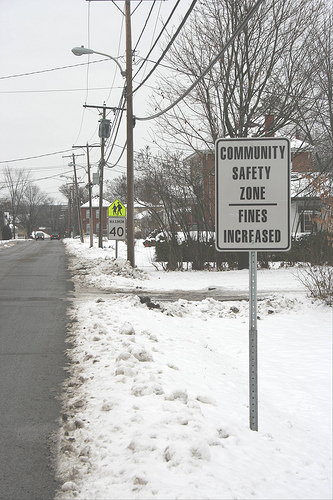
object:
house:
[79, 195, 111, 237]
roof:
[80, 195, 112, 208]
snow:
[268, 299, 333, 498]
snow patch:
[48, 382, 73, 473]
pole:
[248, 250, 258, 432]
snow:
[154, 320, 187, 334]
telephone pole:
[82, 101, 127, 249]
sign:
[107, 198, 126, 217]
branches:
[180, 0, 333, 139]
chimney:
[265, 114, 275, 137]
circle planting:
[289, 252, 333, 307]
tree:
[157, 0, 333, 138]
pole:
[125, 0, 136, 268]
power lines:
[151, 0, 197, 72]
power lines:
[105, 139, 127, 168]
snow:
[78, 452, 130, 500]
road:
[0, 245, 72, 500]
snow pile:
[90, 256, 152, 281]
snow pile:
[162, 296, 229, 318]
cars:
[50, 233, 59, 240]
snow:
[207, 440, 266, 500]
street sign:
[107, 199, 126, 259]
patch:
[267, 353, 326, 387]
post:
[214, 136, 291, 432]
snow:
[258, 302, 333, 500]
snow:
[258, 272, 287, 289]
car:
[34, 232, 45, 241]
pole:
[115, 240, 117, 259]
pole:
[73, 157, 85, 243]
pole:
[87, 147, 94, 248]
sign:
[215, 137, 292, 253]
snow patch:
[61, 317, 76, 376]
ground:
[69, 299, 333, 500]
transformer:
[98, 118, 112, 138]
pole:
[98, 137, 105, 248]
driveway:
[72, 285, 310, 304]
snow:
[162, 273, 193, 287]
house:
[181, 114, 319, 232]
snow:
[92, 198, 99, 206]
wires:
[135, 0, 264, 121]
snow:
[160, 318, 242, 391]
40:
[109, 226, 124, 236]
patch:
[162, 320, 237, 353]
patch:
[165, 270, 198, 290]